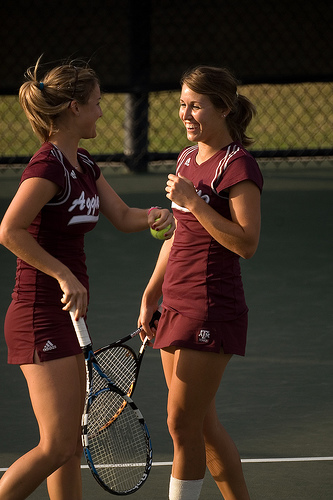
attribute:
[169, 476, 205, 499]
sock — white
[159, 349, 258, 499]
legs — partial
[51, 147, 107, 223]
print — white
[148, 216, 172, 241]
ball — green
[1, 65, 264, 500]
women — smiling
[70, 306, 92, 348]
handle — white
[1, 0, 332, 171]
fence — iron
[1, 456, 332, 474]
line — white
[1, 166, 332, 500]
court — grey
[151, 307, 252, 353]
skirt — marroon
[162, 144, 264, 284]
top — marroon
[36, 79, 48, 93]
hairband — blue